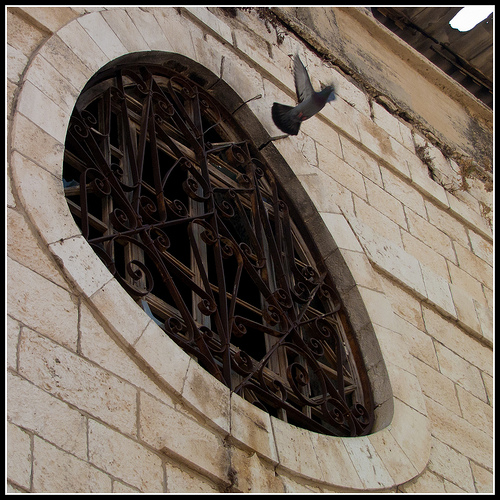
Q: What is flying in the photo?
A: Bird.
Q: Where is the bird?
A: Air.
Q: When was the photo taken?
A: Daytime.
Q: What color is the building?
A: Tan.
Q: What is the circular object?
A: Window.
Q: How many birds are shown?
A: One.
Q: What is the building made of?
A: Bricks.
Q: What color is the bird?
A: Gray.